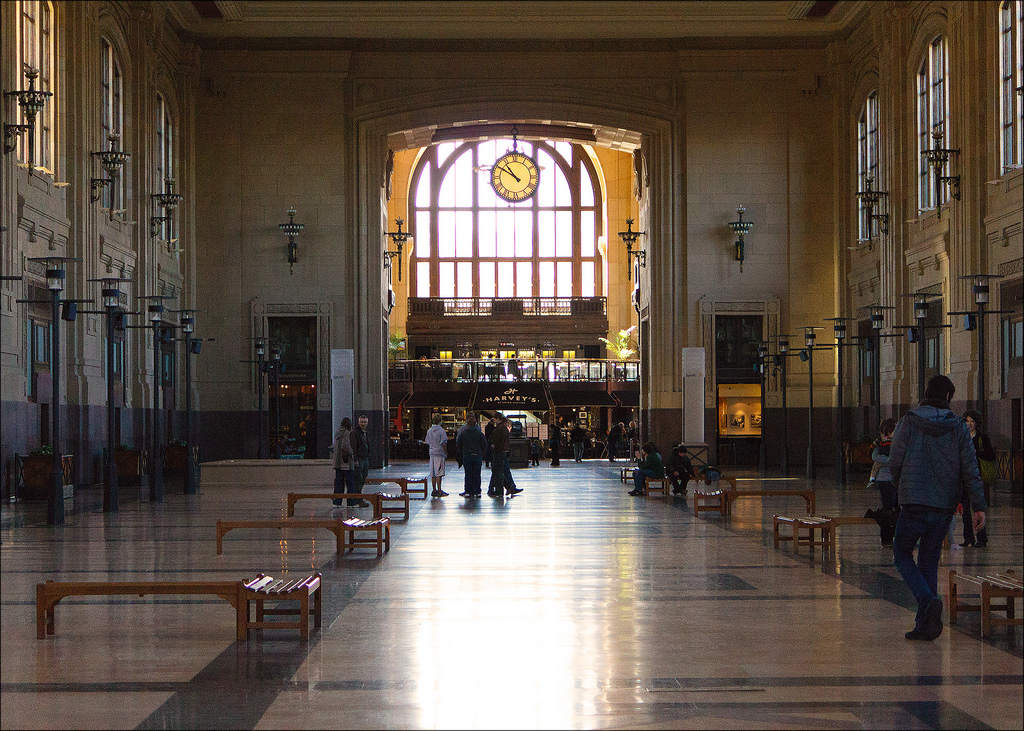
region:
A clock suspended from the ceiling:
[493, 156, 535, 199]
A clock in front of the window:
[499, 158, 535, 197]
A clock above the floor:
[498, 157, 536, 195]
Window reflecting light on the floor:
[451, 552, 544, 720]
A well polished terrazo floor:
[710, 613, 848, 667]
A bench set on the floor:
[253, 575, 308, 596]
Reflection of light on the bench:
[259, 578, 305, 589]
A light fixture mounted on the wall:
[275, 202, 305, 263]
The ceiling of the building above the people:
[391, 6, 560, 36]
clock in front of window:
[474, 141, 557, 211]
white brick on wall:
[674, 97, 748, 202]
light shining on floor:
[346, 444, 644, 692]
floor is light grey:
[342, 507, 777, 686]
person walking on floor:
[839, 353, 995, 686]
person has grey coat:
[847, 387, 988, 533]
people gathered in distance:
[317, 397, 590, 543]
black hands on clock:
[449, 112, 566, 248]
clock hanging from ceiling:
[490, 124, 542, 201]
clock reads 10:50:
[489, 149, 544, 204]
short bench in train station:
[31, 575, 326, 634]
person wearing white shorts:
[423, 411, 450, 495]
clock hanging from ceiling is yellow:
[487, 149, 544, 201]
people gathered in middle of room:
[422, 411, 524, 501]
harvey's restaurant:
[474, 379, 544, 408]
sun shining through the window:
[405, 139, 611, 304]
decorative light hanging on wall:
[275, 200, 308, 278]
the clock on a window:
[482, 144, 549, 212]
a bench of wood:
[12, 558, 345, 663]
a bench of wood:
[196, 507, 402, 559]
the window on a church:
[844, 85, 899, 260]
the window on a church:
[910, 25, 969, 235]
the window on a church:
[8, 8, 72, 187]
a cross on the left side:
[384, 201, 419, 291]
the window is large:
[392, 142, 614, 308]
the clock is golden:
[485, 152, 546, 217]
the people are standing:
[422, 405, 511, 516]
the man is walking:
[870, 358, 991, 625]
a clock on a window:
[448, 125, 574, 232]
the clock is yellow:
[483, 147, 549, 215]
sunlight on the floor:
[359, 515, 686, 727]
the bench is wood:
[23, 548, 337, 649]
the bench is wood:
[203, 505, 403, 567]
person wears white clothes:
[417, 406, 454, 509]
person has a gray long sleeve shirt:
[864, 359, 998, 671]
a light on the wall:
[714, 191, 770, 276]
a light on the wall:
[267, 189, 311, 280]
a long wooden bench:
[29, 568, 264, 646]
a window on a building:
[537, 137, 580, 214]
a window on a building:
[535, 196, 570, 255]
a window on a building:
[432, 258, 472, 325]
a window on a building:
[475, 251, 532, 303]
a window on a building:
[540, 251, 578, 310]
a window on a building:
[578, 201, 594, 253]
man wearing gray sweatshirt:
[422, 411, 454, 498]